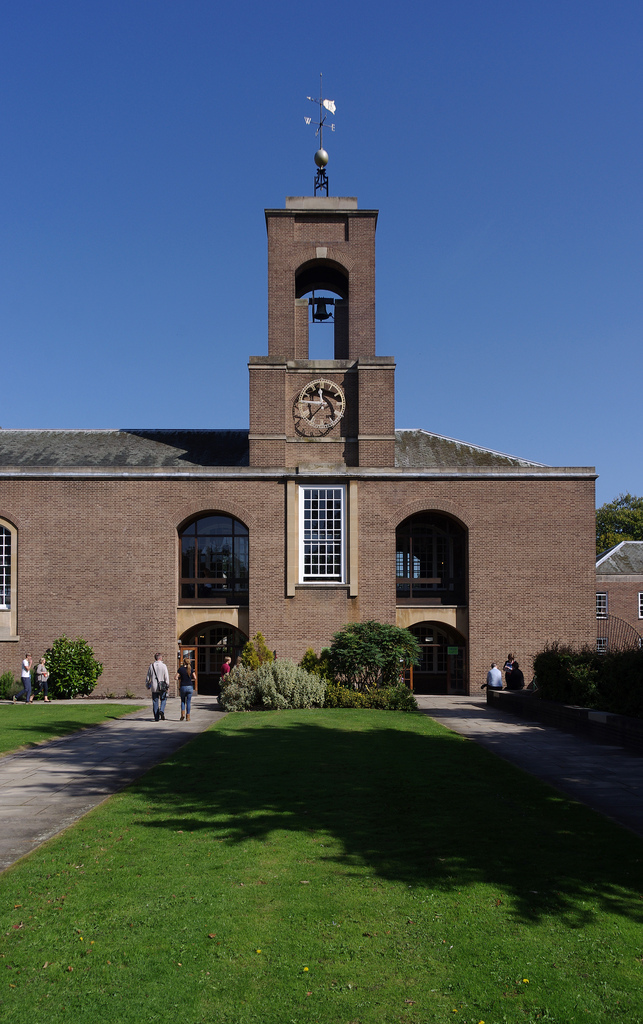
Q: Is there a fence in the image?
A: No, there are no fences.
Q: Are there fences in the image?
A: No, there are no fences.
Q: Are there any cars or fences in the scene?
A: No, there are no fences or cars.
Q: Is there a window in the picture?
A: Yes, there is a window.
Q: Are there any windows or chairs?
A: Yes, there is a window.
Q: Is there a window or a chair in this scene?
A: Yes, there is a window.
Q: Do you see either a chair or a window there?
A: Yes, there is a window.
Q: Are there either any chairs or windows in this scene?
A: Yes, there is a window.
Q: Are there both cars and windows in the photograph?
A: No, there is a window but no cars.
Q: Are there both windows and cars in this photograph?
A: No, there is a window but no cars.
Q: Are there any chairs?
A: No, there are no chairs.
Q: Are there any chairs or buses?
A: No, there are no chairs or buses.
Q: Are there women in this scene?
A: Yes, there is a woman.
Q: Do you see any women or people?
A: Yes, there is a woman.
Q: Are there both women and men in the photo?
A: Yes, there are both a woman and a man.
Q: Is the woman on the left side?
A: Yes, the woman is on the left of the image.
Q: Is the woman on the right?
A: No, the woman is on the left of the image.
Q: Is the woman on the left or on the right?
A: The woman is on the left of the image.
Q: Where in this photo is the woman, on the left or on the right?
A: The woman is on the left of the image.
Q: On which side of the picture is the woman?
A: The woman is on the left of the image.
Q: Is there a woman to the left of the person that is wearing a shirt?
A: Yes, there is a woman to the left of the person.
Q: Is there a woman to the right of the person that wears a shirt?
A: No, the woman is to the left of the person.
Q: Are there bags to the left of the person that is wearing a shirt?
A: No, there is a woman to the left of the person.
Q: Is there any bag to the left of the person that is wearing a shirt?
A: No, there is a woman to the left of the person.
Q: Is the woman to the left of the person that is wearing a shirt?
A: Yes, the woman is to the left of the person.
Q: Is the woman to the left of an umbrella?
A: No, the woman is to the left of the person.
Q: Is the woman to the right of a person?
A: No, the woman is to the left of a person.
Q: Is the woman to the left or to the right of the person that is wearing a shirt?
A: The woman is to the left of the person.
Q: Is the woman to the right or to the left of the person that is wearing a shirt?
A: The woman is to the left of the person.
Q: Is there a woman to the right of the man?
A: Yes, there is a woman to the right of the man.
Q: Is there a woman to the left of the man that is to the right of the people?
A: No, the woman is to the right of the man.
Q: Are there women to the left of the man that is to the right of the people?
A: No, the woman is to the right of the man.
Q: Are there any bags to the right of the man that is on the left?
A: No, there is a woman to the right of the man.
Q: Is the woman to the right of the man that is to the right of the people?
A: Yes, the woman is to the right of the man.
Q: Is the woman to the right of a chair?
A: No, the woman is to the right of the man.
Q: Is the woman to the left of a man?
A: No, the woman is to the right of a man.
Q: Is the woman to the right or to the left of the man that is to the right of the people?
A: The woman is to the right of the man.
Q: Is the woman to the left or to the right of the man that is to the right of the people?
A: The woman is to the right of the man.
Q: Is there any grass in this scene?
A: Yes, there is grass.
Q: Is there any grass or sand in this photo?
A: Yes, there is grass.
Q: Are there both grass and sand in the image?
A: No, there is grass but no sand.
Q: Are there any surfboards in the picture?
A: No, there are no surfboards.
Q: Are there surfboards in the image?
A: No, there are no surfboards.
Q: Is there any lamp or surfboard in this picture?
A: No, there are no surfboards or lamps.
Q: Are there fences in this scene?
A: No, there are no fences.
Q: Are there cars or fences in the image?
A: No, there are no fences or cars.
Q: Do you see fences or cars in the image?
A: No, there are no fences or cars.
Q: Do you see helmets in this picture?
A: No, there are no helmets.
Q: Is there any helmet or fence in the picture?
A: No, there are no helmets or fences.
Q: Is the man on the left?
A: Yes, the man is on the left of the image.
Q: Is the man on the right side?
A: No, the man is on the left of the image.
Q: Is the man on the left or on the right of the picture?
A: The man is on the left of the image.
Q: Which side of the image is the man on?
A: The man is on the left of the image.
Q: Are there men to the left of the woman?
A: Yes, there is a man to the left of the woman.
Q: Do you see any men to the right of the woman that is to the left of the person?
A: No, the man is to the left of the woman.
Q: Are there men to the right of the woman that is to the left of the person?
A: No, the man is to the left of the woman.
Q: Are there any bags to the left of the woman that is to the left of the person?
A: No, there is a man to the left of the woman.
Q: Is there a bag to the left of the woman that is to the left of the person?
A: No, there is a man to the left of the woman.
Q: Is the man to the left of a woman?
A: Yes, the man is to the left of a woman.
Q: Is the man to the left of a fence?
A: No, the man is to the left of a woman.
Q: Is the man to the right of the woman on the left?
A: No, the man is to the left of the woman.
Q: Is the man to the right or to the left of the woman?
A: The man is to the left of the woman.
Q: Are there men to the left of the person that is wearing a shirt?
A: Yes, there is a man to the left of the person.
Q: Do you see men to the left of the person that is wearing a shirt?
A: Yes, there is a man to the left of the person.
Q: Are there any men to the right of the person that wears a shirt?
A: No, the man is to the left of the person.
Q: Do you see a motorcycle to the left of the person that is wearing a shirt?
A: No, there is a man to the left of the person.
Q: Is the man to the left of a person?
A: Yes, the man is to the left of a person.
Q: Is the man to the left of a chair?
A: No, the man is to the left of a person.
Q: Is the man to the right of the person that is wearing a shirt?
A: No, the man is to the left of the person.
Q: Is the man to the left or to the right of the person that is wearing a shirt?
A: The man is to the left of the person.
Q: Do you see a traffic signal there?
A: No, there are no traffic lights.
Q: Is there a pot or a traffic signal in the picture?
A: No, there are no traffic lights or pots.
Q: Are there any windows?
A: Yes, there is a window.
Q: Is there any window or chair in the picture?
A: Yes, there is a window.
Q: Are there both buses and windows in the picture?
A: No, there is a window but no buses.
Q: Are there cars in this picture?
A: No, there are no cars.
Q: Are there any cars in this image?
A: No, there are no cars.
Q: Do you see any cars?
A: No, there are no cars.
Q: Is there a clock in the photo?
A: Yes, there is a clock.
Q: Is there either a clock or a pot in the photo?
A: Yes, there is a clock.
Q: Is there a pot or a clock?
A: Yes, there is a clock.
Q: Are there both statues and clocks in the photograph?
A: No, there is a clock but no statues.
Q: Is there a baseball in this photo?
A: No, there are no baseballs.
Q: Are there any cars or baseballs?
A: No, there are no baseballs or cars.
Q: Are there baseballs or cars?
A: No, there are no baseballs or cars.